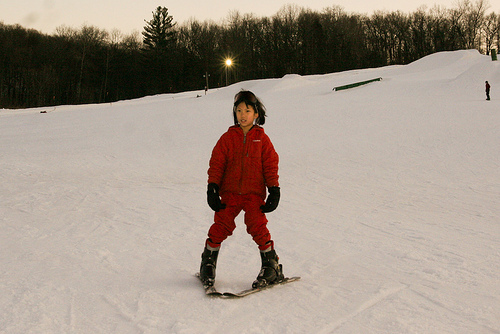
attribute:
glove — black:
[249, 175, 299, 221]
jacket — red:
[190, 128, 294, 226]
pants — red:
[197, 190, 278, 259]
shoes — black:
[191, 235, 293, 305]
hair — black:
[209, 85, 279, 114]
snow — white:
[6, 60, 496, 331]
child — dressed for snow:
[191, 73, 291, 327]